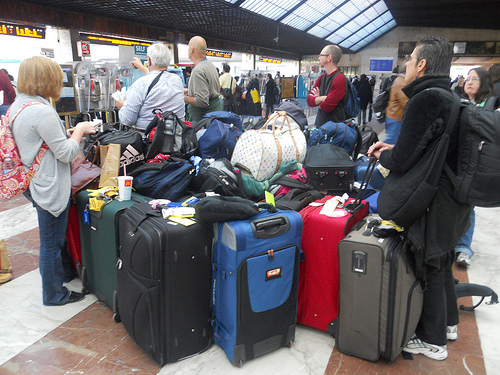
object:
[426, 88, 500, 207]
backpack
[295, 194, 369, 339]
suitcase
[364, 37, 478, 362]
man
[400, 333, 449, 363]
shoe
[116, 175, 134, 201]
cup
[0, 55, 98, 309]
woman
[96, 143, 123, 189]
bag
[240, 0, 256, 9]
window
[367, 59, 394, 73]
sign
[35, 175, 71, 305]
leg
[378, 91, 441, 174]
arm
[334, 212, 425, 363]
luggage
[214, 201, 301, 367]
luggage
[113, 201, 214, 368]
luggage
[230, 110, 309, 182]
purse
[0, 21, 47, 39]
sign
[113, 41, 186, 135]
men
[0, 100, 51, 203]
backpack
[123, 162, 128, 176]
straw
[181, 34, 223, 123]
man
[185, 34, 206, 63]
head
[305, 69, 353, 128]
shirt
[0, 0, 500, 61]
roof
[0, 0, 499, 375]
airport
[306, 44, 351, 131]
man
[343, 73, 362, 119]
backpack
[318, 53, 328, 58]
eyeglasses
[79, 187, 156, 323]
suitcase